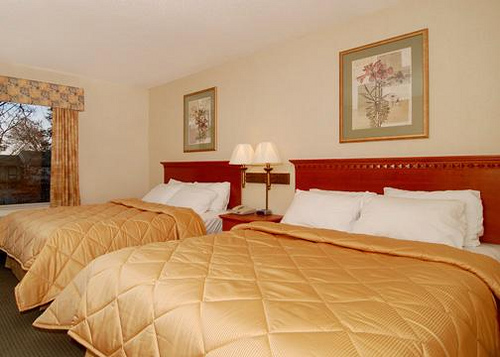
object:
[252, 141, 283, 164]
lampshade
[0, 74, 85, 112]
valance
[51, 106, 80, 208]
drape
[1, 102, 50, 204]
window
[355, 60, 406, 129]
flowers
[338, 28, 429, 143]
picture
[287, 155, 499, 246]
headboard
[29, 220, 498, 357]
comforter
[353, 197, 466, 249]
pillow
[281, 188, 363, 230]
pillow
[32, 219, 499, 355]
bed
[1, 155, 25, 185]
house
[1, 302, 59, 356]
carpet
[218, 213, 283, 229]
end table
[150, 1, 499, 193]
wall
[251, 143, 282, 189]
lamp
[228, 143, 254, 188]
lamp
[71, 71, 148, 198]
wall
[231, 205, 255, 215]
phone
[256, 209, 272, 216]
clock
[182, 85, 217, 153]
picture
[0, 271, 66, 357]
floor